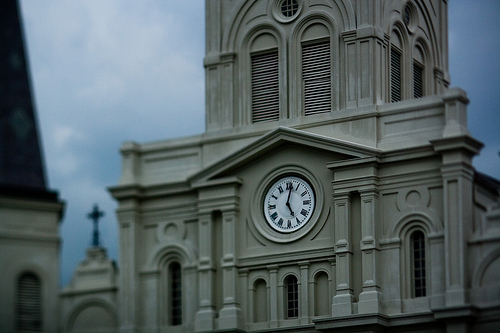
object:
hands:
[282, 177, 298, 232]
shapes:
[5, 38, 46, 153]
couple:
[254, 167, 319, 240]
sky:
[64, 35, 101, 175]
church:
[3, 3, 498, 330]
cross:
[80, 202, 110, 244]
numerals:
[263, 178, 308, 228]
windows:
[166, 260, 183, 328]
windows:
[284, 275, 299, 318]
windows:
[410, 231, 427, 299]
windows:
[279, 1, 298, 16]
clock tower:
[236, 155, 337, 249]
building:
[34, 0, 498, 331]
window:
[240, 10, 340, 125]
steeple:
[3, 2, 59, 219]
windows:
[166, 261, 182, 321]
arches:
[385, 207, 445, 298]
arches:
[277, 264, 307, 319]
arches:
[149, 243, 191, 331]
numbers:
[252, 159, 334, 257]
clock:
[257, 172, 320, 235]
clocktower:
[104, 0, 498, 331]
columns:
[189, 153, 384, 329]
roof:
[0, 182, 69, 213]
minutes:
[284, 179, 300, 209]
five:
[283, 201, 305, 228]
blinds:
[249, 46, 281, 125]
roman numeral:
[292, 178, 305, 193]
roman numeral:
[284, 215, 292, 229]